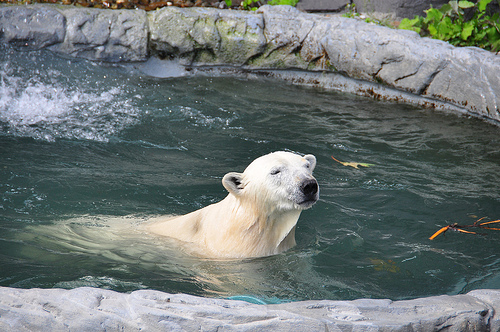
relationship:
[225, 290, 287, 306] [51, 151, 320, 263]
object on bear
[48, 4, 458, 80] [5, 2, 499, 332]
stone on pool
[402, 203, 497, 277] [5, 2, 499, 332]
item on pool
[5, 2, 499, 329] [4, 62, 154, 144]
pool on churning water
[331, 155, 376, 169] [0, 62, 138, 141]
leaf on churning water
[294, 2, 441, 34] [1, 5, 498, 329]
wall outside of tub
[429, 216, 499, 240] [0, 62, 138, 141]
item in churning water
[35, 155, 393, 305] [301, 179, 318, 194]
bear with a nose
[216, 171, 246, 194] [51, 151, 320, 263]
ear on bear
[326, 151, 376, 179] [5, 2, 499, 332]
leaf in pool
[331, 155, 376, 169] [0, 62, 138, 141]
leaf in churning water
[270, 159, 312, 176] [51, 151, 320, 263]
eyes of bear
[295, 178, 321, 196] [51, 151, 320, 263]
nose of bear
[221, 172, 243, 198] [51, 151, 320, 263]
ear of bear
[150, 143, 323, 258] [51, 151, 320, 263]
fur of bear